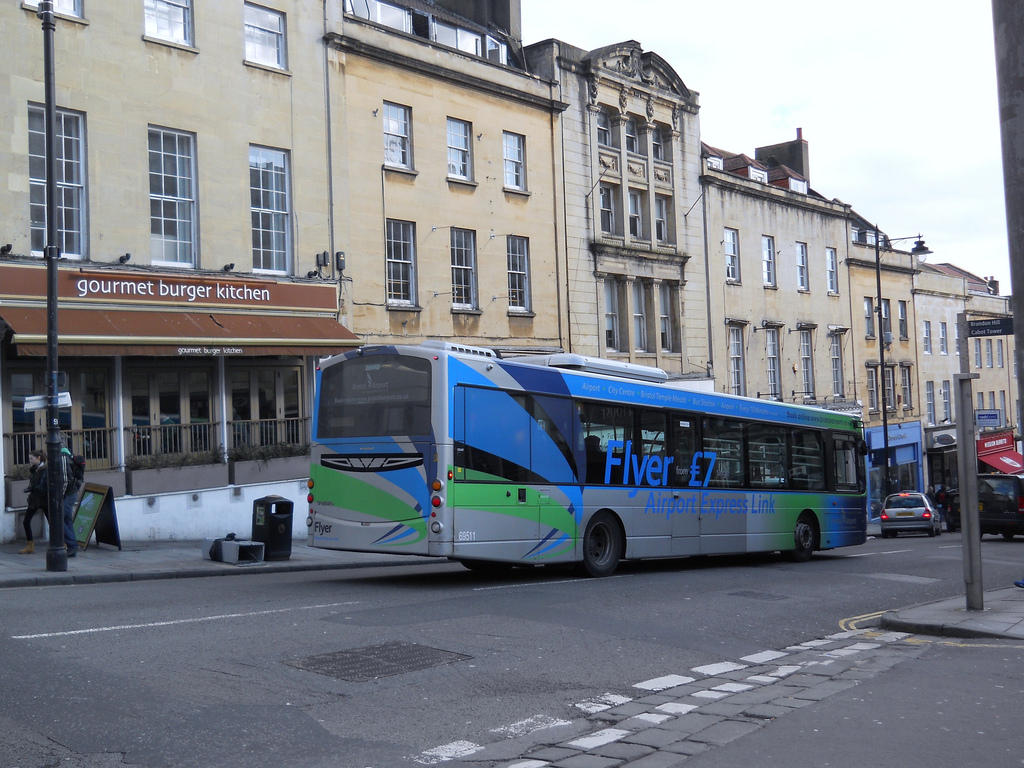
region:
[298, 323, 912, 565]
green blue and gray passenger bus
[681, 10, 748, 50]
white clouds in blue sky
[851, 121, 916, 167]
white clouds in blue sky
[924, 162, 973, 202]
white clouds in blue sky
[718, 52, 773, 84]
white clouds in blue sky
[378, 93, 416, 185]
window in tan building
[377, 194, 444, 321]
window in tan building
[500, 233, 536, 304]
window in tan building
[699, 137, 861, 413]
building on the side of the road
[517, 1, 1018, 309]
the sky above the buildings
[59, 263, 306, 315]
a sign on the structure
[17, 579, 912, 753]
the road on the ground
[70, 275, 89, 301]
one character on the sign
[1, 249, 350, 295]
the top of the sign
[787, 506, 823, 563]
the vehicles front tire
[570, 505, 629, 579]
the vehicles rear tire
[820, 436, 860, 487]
the front windshield of the vehicle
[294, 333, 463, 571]
the rear part of the vehicle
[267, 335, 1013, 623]
Vehicles on the road.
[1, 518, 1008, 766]
The road.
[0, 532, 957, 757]
White lines on the road.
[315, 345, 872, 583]
A grey, blue, and green bus.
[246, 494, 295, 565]
A trash bin on the sidewalk.